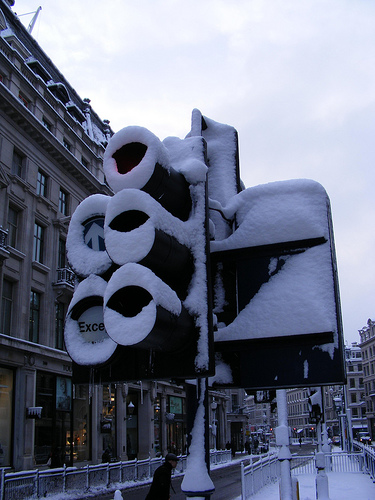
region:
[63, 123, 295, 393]
signal light covered in white snow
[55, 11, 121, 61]
white clouds in blue sky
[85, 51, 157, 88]
white clouds in blue sky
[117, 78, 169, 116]
white clouds in blue sky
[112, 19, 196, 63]
white clouds in blue sky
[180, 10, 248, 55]
white clouds in blue sky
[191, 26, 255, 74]
white clouds in blue sky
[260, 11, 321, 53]
white clouds in blue sky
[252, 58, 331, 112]
white clouds in blue sky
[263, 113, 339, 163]
white clouds in blue sky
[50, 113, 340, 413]
traffic light covered with snow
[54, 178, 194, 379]
traffic light covered with snow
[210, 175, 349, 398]
traffic light covered with snow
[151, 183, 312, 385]
traffic light covered with snow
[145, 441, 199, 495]
a man crossing the street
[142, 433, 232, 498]
a man crossing the street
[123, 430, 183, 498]
a man crossing the street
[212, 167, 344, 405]
signal light covered with snow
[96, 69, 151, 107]
white clouds in blue sky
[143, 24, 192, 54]
white clouds in blue sky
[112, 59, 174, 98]
white clouds in blue sky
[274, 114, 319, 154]
white clouds in blue sky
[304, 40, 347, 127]
white clouds in blue sky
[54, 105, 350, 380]
snow all over sign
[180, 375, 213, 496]
a black pole for sign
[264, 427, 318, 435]
red lights along street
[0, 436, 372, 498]
a fence down street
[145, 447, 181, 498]
a man walking on street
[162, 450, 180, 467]
a hat on head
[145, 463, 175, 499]
a black coat on man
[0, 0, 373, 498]
tall buildings on both sides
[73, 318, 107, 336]
exce on the sign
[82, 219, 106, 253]
arrow pointing up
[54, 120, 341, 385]
Snow covering street light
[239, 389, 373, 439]
Buildings in the background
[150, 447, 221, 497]
Man beside a pole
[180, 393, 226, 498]
Pole covered in snow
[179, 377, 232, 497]
Snow covering black pole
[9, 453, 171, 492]
Railings along the sidewalk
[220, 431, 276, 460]
People in the distance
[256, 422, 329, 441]
Red lights in the distance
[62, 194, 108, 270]
Forward arrow covered in snow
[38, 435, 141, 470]
Person walking along the sidewalk